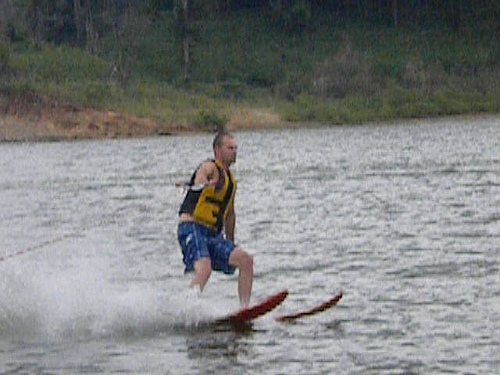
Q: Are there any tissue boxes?
A: No, there are no tissue boxes.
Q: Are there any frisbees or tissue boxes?
A: No, there are no tissue boxes or frisbees.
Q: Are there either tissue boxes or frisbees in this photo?
A: No, there are no tissue boxes or frisbees.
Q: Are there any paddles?
A: No, there are no paddles.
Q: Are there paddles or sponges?
A: No, there are no paddles or sponges.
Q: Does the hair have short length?
A: Yes, the hair is short.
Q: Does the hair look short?
A: Yes, the hair is short.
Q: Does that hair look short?
A: Yes, the hair is short.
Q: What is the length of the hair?
A: The hair is short.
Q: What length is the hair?
A: The hair is short.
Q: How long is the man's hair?
A: The hair is short.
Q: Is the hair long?
A: No, the hair is short.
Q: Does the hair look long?
A: No, the hair is short.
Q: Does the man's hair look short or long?
A: The hair is short.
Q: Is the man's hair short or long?
A: The hair is short.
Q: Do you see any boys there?
A: No, there are no boys.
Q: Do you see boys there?
A: No, there are no boys.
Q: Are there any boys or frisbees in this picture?
A: No, there are no boys or frisbees.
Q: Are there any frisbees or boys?
A: No, there are no boys or frisbees.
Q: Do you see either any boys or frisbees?
A: No, there are no boys or frisbees.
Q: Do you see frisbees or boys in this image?
A: No, there are no boys or frisbees.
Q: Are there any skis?
A: Yes, there are skis.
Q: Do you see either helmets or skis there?
A: Yes, there are skis.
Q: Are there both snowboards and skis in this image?
A: No, there are skis but no snowboards.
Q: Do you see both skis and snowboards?
A: No, there are skis but no snowboards.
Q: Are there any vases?
A: No, there are no vases.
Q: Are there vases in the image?
A: No, there are no vases.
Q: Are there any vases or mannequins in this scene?
A: No, there are no vases or mannequins.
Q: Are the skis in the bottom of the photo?
A: Yes, the skis are in the bottom of the image.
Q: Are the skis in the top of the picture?
A: No, the skis are in the bottom of the image.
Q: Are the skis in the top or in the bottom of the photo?
A: The skis are in the bottom of the image.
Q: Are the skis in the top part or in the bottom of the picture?
A: The skis are in the bottom of the image.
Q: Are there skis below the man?
A: Yes, there are skis below the man.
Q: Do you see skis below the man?
A: Yes, there are skis below the man.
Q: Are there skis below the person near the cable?
A: Yes, there are skis below the man.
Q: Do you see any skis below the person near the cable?
A: Yes, there are skis below the man.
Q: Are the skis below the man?
A: Yes, the skis are below the man.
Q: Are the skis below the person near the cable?
A: Yes, the skis are below the man.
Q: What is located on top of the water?
A: The skis are on top of the water.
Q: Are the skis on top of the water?
A: Yes, the skis are on top of the water.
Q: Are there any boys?
A: No, there are no boys.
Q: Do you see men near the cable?
A: Yes, there is a man near the cable.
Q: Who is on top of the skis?
A: The man is on top of the skis.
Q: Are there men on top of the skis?
A: Yes, there is a man on top of the skis.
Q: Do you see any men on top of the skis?
A: Yes, there is a man on top of the skis.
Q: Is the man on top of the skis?
A: Yes, the man is on top of the skis.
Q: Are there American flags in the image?
A: No, there are no American flags.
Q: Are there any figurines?
A: No, there are no figurines.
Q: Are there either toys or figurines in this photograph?
A: No, there are no figurines or toys.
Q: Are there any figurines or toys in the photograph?
A: No, there are no figurines or toys.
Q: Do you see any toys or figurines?
A: No, there are no figurines or toys.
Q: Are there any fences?
A: No, there are no fences.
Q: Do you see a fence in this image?
A: No, there are no fences.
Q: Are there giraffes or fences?
A: No, there are no fences or giraffes.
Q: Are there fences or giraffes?
A: No, there are no fences or giraffes.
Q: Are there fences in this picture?
A: No, there are no fences.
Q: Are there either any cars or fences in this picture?
A: No, there are no fences or cars.